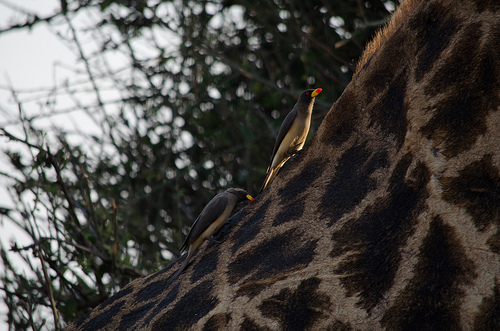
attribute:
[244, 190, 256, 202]
beak — orange 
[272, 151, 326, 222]
spot — brown 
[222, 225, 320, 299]
spot — brown 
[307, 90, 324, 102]
beak — orange 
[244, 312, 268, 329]
spot — brown 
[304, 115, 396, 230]
spot — brown 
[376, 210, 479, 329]
spot — brown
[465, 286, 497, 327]
spot — brown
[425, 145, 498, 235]
spot — brown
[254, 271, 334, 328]
spot — brown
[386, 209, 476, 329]
spot — brown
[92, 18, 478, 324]
spots — brown